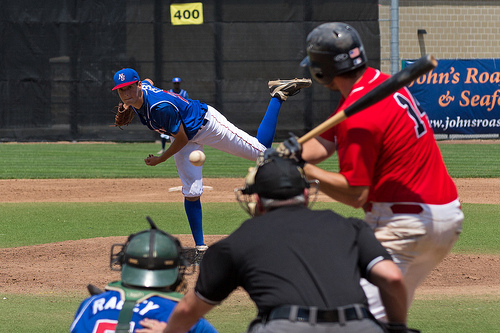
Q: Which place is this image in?
A: It is at the stadium.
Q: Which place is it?
A: It is a stadium.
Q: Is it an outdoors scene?
A: Yes, it is outdoors.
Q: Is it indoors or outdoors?
A: It is outdoors.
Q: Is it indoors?
A: No, it is outdoors.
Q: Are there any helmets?
A: Yes, there is a helmet.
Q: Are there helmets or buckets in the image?
A: Yes, there is a helmet.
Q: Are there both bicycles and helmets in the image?
A: No, there is a helmet but no bikes.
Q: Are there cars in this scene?
A: No, there are no cars.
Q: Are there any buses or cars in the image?
A: No, there are no cars or buses.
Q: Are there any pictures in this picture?
A: No, there are no pictures.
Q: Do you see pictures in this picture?
A: No, there are no pictures.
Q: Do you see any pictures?
A: No, there are no pictures.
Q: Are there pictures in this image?
A: No, there are no pictures.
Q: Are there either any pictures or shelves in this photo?
A: No, there are no pictures or shelves.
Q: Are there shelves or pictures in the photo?
A: No, there are no pictures or shelves.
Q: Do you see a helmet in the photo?
A: Yes, there is a helmet.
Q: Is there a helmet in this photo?
A: Yes, there is a helmet.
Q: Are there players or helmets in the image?
A: Yes, there is a helmet.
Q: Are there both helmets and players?
A: Yes, there are both a helmet and a player.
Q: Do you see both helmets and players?
A: Yes, there are both a helmet and a player.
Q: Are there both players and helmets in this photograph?
A: Yes, there are both a helmet and a player.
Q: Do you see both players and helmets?
A: Yes, there are both a helmet and a player.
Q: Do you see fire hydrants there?
A: No, there are no fire hydrants.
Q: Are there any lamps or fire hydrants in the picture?
A: No, there are no fire hydrants or lamps.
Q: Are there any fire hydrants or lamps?
A: No, there are no fire hydrants or lamps.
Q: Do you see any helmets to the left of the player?
A: Yes, there is a helmet to the left of the player.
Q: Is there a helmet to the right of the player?
A: No, the helmet is to the left of the player.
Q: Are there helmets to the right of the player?
A: No, the helmet is to the left of the player.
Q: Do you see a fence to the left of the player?
A: No, there is a helmet to the left of the player.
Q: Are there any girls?
A: No, there are no girls.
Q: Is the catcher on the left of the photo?
A: Yes, the catcher is on the left of the image.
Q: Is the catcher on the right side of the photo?
A: No, the catcher is on the left of the image.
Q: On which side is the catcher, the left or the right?
A: The catcher is on the left of the image.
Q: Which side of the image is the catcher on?
A: The catcher is on the left of the image.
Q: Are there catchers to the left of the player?
A: Yes, there is a catcher to the left of the player.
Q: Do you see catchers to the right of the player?
A: No, the catcher is to the left of the player.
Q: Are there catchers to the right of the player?
A: No, the catcher is to the left of the player.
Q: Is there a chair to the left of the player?
A: No, there is a catcher to the left of the player.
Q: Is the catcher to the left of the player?
A: Yes, the catcher is to the left of the player.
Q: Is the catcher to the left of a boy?
A: No, the catcher is to the left of the player.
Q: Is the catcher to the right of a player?
A: No, the catcher is to the left of a player.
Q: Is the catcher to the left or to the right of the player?
A: The catcher is to the left of the player.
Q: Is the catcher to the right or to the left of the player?
A: The catcher is to the left of the player.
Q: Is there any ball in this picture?
A: Yes, there is a ball.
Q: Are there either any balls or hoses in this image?
A: Yes, there is a ball.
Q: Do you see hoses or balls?
A: Yes, there is a ball.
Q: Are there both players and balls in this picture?
A: Yes, there are both a ball and a player.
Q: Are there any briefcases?
A: No, there are no briefcases.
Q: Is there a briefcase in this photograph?
A: No, there are no briefcases.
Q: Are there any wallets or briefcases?
A: No, there are no briefcases or wallets.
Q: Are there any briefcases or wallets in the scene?
A: No, there are no briefcases or wallets.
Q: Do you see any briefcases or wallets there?
A: No, there are no briefcases or wallets.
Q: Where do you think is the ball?
A: The ball is in the stadium.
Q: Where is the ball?
A: The ball is in the stadium.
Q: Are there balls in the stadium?
A: Yes, there is a ball in the stadium.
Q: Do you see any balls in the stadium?
A: Yes, there is a ball in the stadium.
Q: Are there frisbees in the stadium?
A: No, there is a ball in the stadium.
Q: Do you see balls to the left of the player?
A: Yes, there is a ball to the left of the player.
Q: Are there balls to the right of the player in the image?
A: No, the ball is to the left of the player.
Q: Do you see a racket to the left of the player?
A: No, there is a ball to the left of the player.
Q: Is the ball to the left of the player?
A: Yes, the ball is to the left of the player.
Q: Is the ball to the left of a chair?
A: No, the ball is to the left of the player.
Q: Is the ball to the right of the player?
A: No, the ball is to the left of the player.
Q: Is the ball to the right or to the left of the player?
A: The ball is to the left of the player.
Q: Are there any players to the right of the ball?
A: Yes, there is a player to the right of the ball.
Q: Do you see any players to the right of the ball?
A: Yes, there is a player to the right of the ball.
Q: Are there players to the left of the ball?
A: No, the player is to the right of the ball.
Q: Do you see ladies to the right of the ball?
A: No, there is a player to the right of the ball.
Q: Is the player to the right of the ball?
A: Yes, the player is to the right of the ball.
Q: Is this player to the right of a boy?
A: No, the player is to the right of the ball.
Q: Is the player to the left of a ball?
A: No, the player is to the right of a ball.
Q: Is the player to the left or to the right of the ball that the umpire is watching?
A: The player is to the right of the ball.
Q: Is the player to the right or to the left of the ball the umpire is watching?
A: The player is to the right of the ball.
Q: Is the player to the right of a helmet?
A: Yes, the player is to the right of a helmet.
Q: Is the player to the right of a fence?
A: No, the player is to the right of a helmet.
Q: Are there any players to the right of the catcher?
A: Yes, there is a player to the right of the catcher.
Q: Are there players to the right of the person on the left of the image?
A: Yes, there is a player to the right of the catcher.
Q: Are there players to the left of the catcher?
A: No, the player is to the right of the catcher.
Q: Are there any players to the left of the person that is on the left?
A: No, the player is to the right of the catcher.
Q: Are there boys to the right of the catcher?
A: No, there is a player to the right of the catcher.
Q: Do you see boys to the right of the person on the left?
A: No, there is a player to the right of the catcher.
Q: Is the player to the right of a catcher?
A: Yes, the player is to the right of a catcher.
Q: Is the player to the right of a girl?
A: No, the player is to the right of a catcher.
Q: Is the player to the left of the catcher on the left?
A: No, the player is to the right of the catcher.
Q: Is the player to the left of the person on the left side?
A: No, the player is to the right of the catcher.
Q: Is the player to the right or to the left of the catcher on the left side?
A: The player is to the right of the catcher.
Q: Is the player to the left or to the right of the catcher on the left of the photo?
A: The player is to the right of the catcher.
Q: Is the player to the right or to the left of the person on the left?
A: The player is to the right of the catcher.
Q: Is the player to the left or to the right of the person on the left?
A: The player is to the right of the catcher.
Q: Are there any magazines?
A: No, there are no magazines.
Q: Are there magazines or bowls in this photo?
A: No, there are no magazines or bowls.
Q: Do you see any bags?
A: No, there are no bags.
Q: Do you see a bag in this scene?
A: No, there are no bags.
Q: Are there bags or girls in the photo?
A: No, there are no bags or girls.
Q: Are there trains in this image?
A: No, there are no trains.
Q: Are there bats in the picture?
A: Yes, there is a bat.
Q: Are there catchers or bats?
A: Yes, there is a bat.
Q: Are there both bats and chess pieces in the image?
A: No, there is a bat but no chess pieces.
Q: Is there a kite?
A: No, there are no kites.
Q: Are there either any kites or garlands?
A: No, there are no kites or garlands.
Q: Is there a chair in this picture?
A: No, there are no chairs.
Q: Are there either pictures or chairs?
A: No, there are no chairs or pictures.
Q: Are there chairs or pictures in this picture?
A: No, there are no chairs or pictures.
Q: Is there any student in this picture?
A: No, there are no students.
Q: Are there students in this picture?
A: No, there are no students.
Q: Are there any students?
A: No, there are no students.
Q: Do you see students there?
A: No, there are no students.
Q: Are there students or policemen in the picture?
A: No, there are no students or policemen.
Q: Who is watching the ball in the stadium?
A: The umpire is watching the ball.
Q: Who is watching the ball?
A: The umpire is watching the ball.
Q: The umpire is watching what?
A: The umpire is watching the ball.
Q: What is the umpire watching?
A: The umpire is watching the ball.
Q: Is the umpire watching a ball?
A: Yes, the umpire is watching a ball.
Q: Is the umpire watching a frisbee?
A: No, the umpire is watching a ball.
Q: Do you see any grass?
A: Yes, there is grass.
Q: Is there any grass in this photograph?
A: Yes, there is grass.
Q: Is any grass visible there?
A: Yes, there is grass.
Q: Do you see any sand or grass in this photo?
A: Yes, there is grass.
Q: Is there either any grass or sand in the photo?
A: Yes, there is grass.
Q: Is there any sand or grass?
A: Yes, there is grass.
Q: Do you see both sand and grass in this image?
A: No, there is grass but no sand.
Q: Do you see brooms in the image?
A: No, there are no brooms.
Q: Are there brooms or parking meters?
A: No, there are no brooms or parking meters.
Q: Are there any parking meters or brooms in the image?
A: No, there are no brooms or parking meters.